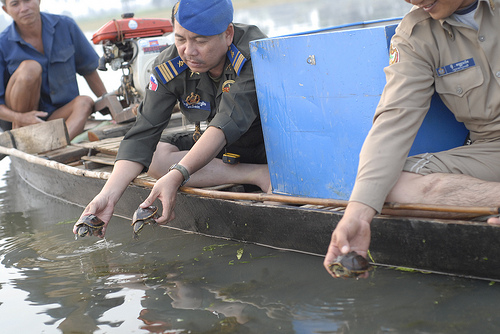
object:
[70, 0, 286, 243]
man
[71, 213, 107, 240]
turtle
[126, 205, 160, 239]
turtle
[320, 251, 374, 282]
turtle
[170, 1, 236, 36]
beret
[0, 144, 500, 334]
water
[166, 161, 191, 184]
watch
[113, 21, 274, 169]
uniform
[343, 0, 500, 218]
uniform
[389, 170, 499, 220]
man's leg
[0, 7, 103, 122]
shirt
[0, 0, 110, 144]
man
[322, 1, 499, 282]
men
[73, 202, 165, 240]
two turtles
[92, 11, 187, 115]
boat motor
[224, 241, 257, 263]
vegetation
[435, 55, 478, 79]
id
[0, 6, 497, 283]
boat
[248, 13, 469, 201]
box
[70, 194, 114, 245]
man's hand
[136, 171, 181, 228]
man's hand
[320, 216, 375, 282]
man's hand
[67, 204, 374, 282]
three turtles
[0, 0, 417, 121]
sky